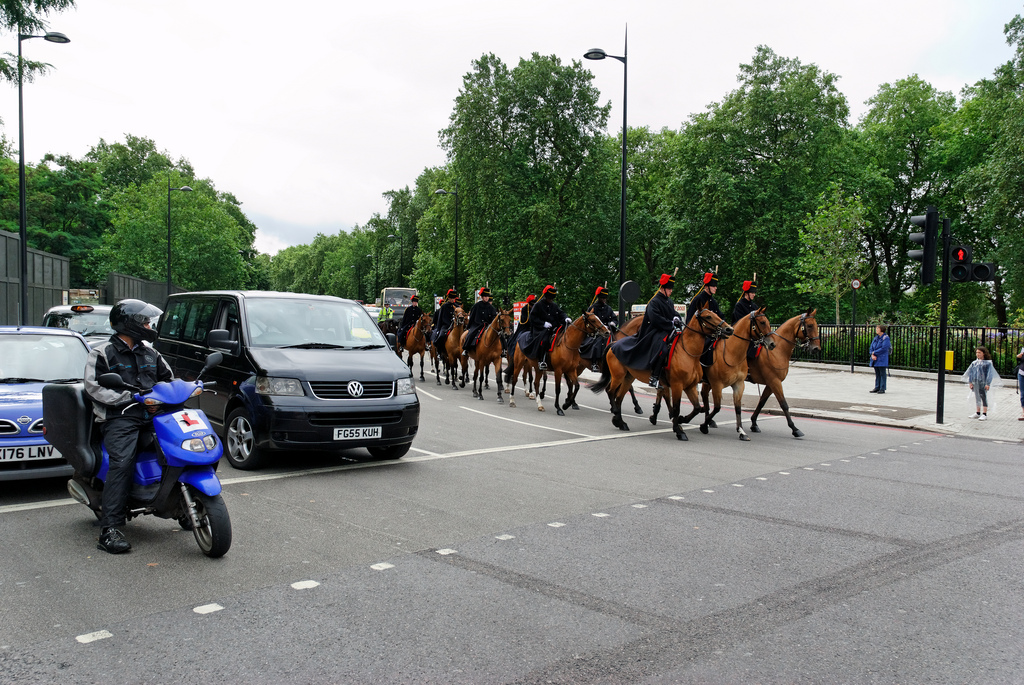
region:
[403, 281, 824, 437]
Long row of brown horse's being ridden down the road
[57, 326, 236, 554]
Blue Motorbike on the road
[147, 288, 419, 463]
Blue VW Van on the road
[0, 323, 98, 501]
Blue Nissan car on the road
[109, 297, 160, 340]
Black motorcycle helmet on mans head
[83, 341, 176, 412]
Black and gray jacket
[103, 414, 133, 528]
Black pants covering left leg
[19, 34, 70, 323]
Street lamp on a tall pole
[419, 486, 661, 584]
white lines on ground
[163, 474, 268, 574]
front tire of bike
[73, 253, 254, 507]
man looking to left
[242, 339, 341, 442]
front light on car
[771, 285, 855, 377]
head of the horse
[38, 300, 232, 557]
man on blue moped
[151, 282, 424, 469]
black van at intersection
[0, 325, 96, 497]
light blue car behind moped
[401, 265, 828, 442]
group of horses at intersection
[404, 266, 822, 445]
men in black capes on horses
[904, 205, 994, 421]
traffic light at intersection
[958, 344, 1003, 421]
kid standing at intersection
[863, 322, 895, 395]
person standing on sidewalk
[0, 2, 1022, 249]
white cloudy sky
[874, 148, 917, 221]
green leaves on the tree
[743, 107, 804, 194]
green leaves on the tree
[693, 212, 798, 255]
green leaves on the tree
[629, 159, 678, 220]
green leaves on the tree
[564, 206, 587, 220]
green leaves on the tree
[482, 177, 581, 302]
green leaves on the tree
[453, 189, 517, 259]
green leaves on the tree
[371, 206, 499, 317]
green leaves on the tree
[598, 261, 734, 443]
policeman wearing black and red on a horse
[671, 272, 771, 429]
policeman wearing black and red on a horse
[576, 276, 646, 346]
policeman wearing black and red on a horse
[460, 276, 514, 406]
policeman wearing black and red on a horse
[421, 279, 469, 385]
policeman wearing black and red on a horse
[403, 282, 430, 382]
policeman wearing black and red on a horse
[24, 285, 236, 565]
man on scooter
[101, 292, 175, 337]
black colored helmet